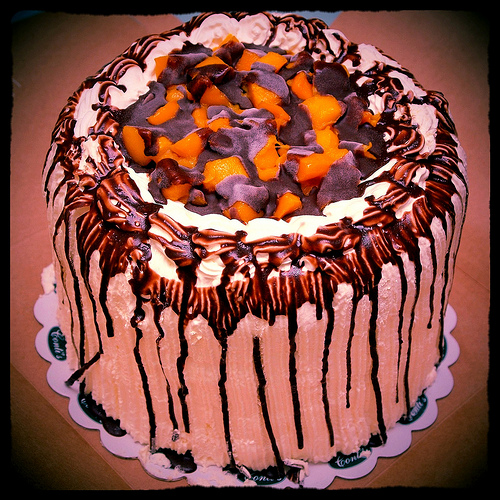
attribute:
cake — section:
[57, 22, 468, 384]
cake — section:
[48, 28, 358, 387]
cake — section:
[59, 19, 464, 460]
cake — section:
[82, 22, 482, 436]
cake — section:
[192, 161, 483, 451]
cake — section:
[52, 126, 294, 458]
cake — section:
[168, 64, 426, 244]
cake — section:
[298, 150, 442, 361]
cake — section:
[203, 219, 385, 489]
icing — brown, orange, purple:
[118, 40, 381, 221]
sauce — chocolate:
[83, 151, 154, 273]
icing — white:
[43, 91, 124, 423]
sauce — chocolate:
[64, 197, 430, 332]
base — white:
[29, 260, 462, 489]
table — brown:
[12, 11, 484, 487]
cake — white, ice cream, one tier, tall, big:
[38, 10, 468, 474]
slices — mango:
[289, 67, 346, 178]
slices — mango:
[121, 116, 250, 185]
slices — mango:
[194, 33, 289, 74]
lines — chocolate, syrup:
[126, 290, 192, 451]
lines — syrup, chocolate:
[343, 287, 385, 439]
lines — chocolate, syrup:
[283, 299, 337, 449]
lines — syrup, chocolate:
[211, 330, 288, 466]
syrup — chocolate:
[134, 266, 354, 334]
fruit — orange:
[120, 31, 383, 222]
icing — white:
[41, 133, 469, 472]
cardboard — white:
[32, 290, 461, 489]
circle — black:
[47, 325, 68, 362]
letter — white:
[50, 327, 65, 340]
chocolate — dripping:
[285, 285, 304, 449]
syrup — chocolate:
[41, 9, 471, 472]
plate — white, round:
[31, 287, 460, 487]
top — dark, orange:
[113, 34, 389, 222]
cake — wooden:
[64, 49, 445, 476]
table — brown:
[4, 22, 119, 97]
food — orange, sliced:
[128, 55, 319, 172]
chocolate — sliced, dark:
[221, 120, 308, 174]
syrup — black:
[76, 320, 387, 490]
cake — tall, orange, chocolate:
[37, 60, 428, 410]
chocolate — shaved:
[310, 163, 359, 196]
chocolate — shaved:
[224, 180, 275, 217]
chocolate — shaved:
[128, 152, 225, 212]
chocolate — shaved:
[166, 90, 222, 149]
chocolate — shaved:
[49, 324, 108, 379]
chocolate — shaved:
[205, 60, 282, 130]